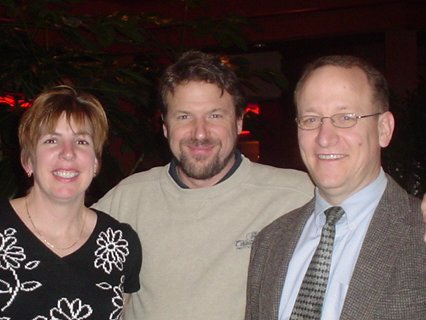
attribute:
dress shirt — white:
[297, 194, 374, 314]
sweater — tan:
[144, 182, 260, 307]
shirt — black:
[3, 192, 143, 318]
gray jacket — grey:
[260, 201, 415, 316]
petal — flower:
[113, 240, 128, 257]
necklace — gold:
[22, 194, 88, 249]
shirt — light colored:
[101, 142, 322, 317]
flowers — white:
[0, 225, 25, 269]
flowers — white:
[47, 294, 93, 318]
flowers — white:
[107, 273, 126, 318]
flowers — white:
[92, 227, 130, 272]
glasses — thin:
[292, 111, 382, 128]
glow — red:
[217, 55, 260, 159]